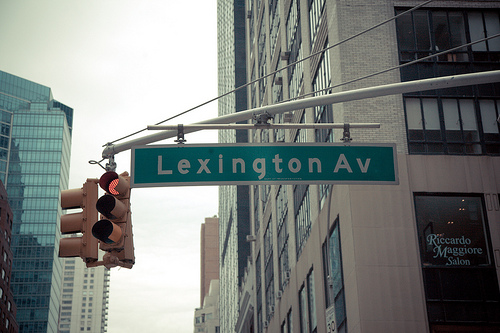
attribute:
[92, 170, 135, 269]
signal — glowing, yellow, traffic, red color, hanging, red, red colro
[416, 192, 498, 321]
window — white, reflecting, salon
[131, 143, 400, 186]
sign — white, hanging, green, rectangular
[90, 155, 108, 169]
wire — connected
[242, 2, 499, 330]
building — white, reflecting, full, glass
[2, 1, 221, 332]
sky — cloudy, overcast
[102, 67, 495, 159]
pole — horizontal, metal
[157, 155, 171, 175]
writing — whtie